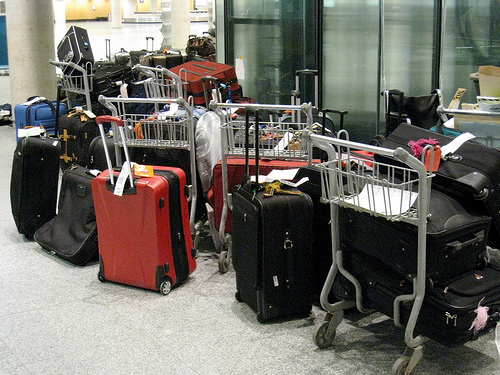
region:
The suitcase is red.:
[77, 101, 213, 296]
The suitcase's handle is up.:
[84, 101, 151, 208]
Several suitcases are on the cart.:
[292, 111, 495, 370]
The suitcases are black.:
[325, 105, 496, 354]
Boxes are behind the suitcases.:
[435, 55, 499, 135]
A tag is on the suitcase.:
[93, 151, 155, 211]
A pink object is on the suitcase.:
[450, 290, 495, 345]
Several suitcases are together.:
[2, 20, 258, 307]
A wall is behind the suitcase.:
[212, 2, 497, 148]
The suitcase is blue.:
[5, 85, 78, 147]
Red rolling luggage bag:
[86, 160, 201, 297]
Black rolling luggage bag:
[230, 173, 315, 330]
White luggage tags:
[246, 161, 308, 194]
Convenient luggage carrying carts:
[303, 125, 450, 374]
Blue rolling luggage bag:
[7, 93, 65, 143]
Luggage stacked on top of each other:
[23, 23, 260, 189]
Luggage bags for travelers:
[15, 21, 495, 331]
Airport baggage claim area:
[115, 0, 206, 25]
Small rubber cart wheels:
[295, 320, 355, 360]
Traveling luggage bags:
[0, 0, 496, 346]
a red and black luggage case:
[87, 159, 199, 299]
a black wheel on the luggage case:
[156, 272, 177, 299]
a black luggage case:
[225, 175, 324, 328]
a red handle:
[90, 107, 127, 132]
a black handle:
[238, 99, 267, 126]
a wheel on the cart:
[311, 318, 341, 350]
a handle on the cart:
[303, 122, 425, 181]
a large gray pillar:
[1, 0, 66, 122]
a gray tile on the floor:
[1, 294, 150, 366]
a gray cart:
[301, 119, 495, 374]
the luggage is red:
[80, 123, 257, 365]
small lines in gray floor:
[64, 292, 140, 327]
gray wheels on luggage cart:
[312, 311, 346, 343]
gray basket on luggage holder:
[285, 119, 457, 246]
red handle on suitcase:
[90, 106, 133, 131]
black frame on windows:
[418, 18, 453, 90]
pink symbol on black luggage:
[466, 297, 497, 339]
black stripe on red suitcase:
[142, 156, 199, 268]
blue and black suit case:
[6, 91, 76, 132]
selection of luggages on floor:
[60, 51, 429, 322]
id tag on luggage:
[101, 158, 143, 199]